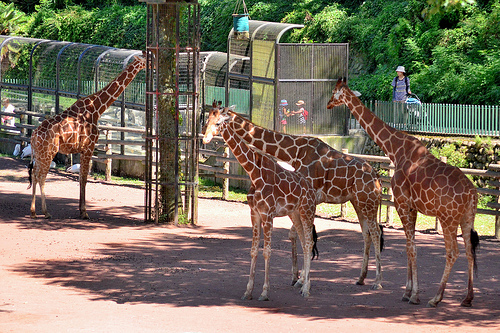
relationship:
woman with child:
[390, 66, 414, 101] [409, 105, 420, 118]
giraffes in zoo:
[203, 99, 384, 259] [7, 57, 499, 261]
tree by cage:
[157, 13, 178, 220] [140, 1, 202, 225]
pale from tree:
[228, 12, 254, 40] [157, 13, 178, 220]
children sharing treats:
[274, 96, 308, 135] [285, 108, 297, 121]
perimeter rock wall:
[328, 122, 498, 143] [361, 138, 497, 166]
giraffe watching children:
[324, 77, 486, 254] [274, 96, 308, 135]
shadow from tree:
[140, 236, 218, 296] [157, 13, 178, 220]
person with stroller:
[391, 63, 406, 101] [404, 94, 431, 129]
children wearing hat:
[274, 96, 308, 135] [395, 63, 405, 74]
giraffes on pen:
[203, 99, 384, 259] [9, 39, 64, 112]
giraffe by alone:
[324, 77, 486, 254] [22, 54, 151, 220]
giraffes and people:
[203, 99, 384, 259] [386, 59, 426, 129]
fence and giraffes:
[101, 126, 143, 179] [203, 99, 384, 259]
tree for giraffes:
[157, 13, 178, 220] [203, 99, 384, 259]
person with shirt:
[391, 63, 406, 101] [392, 78, 406, 100]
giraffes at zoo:
[203, 99, 384, 259] [7, 57, 499, 261]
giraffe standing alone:
[324, 77, 486, 254] [22, 54, 125, 214]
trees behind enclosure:
[33, 7, 139, 40] [4, 32, 171, 117]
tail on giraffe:
[27, 137, 34, 191] [324, 77, 486, 254]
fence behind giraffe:
[101, 126, 143, 179] [324, 77, 486, 254]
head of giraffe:
[324, 78, 357, 118] [324, 77, 486, 254]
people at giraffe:
[386, 59, 426, 129] [324, 77, 486, 254]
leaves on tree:
[323, 13, 332, 33] [157, 13, 178, 220]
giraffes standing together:
[203, 99, 384, 259] [204, 76, 481, 250]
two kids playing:
[274, 91, 310, 136] [274, 95, 307, 119]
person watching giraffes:
[391, 63, 406, 101] [203, 99, 384, 259]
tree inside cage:
[157, 13, 178, 220] [140, 1, 202, 225]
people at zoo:
[386, 59, 426, 129] [7, 57, 499, 261]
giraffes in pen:
[203, 99, 384, 259] [9, 39, 64, 112]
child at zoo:
[409, 105, 420, 118] [7, 57, 499, 261]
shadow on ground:
[140, 236, 218, 296] [3, 219, 228, 333]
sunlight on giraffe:
[61, 118, 82, 142] [324, 77, 486, 254]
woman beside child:
[390, 66, 414, 101] [409, 105, 420, 118]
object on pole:
[230, 1, 252, 42] [188, 4, 202, 157]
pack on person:
[302, 109, 307, 120] [391, 63, 406, 101]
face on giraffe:
[200, 111, 225, 148] [324, 77, 486, 254]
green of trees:
[95, 17, 111, 29] [33, 7, 139, 40]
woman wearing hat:
[390, 66, 414, 101] [395, 63, 405, 74]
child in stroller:
[409, 105, 420, 118] [404, 94, 431, 129]